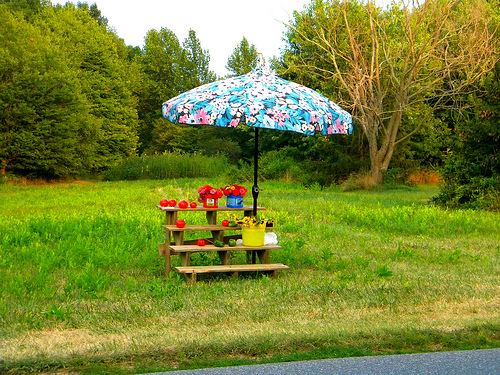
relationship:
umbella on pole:
[162, 52, 354, 136] [248, 126, 265, 263]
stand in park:
[160, 195, 275, 286] [17, 28, 455, 339]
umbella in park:
[162, 52, 354, 136] [17, 28, 455, 339]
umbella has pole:
[162, 52, 354, 136] [232, 119, 272, 220]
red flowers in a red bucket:
[197, 184, 219, 196] [202, 196, 220, 208]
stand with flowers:
[158, 206, 290, 284] [229, 209, 271, 245]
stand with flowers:
[158, 206, 290, 284] [221, 181, 246, 208]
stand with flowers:
[158, 206, 290, 284] [198, 182, 223, 205]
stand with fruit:
[158, 206, 290, 284] [198, 233, 208, 245]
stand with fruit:
[158, 206, 290, 284] [221, 217, 231, 228]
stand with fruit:
[158, 206, 290, 284] [173, 215, 187, 230]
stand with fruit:
[158, 206, 290, 284] [178, 197, 188, 208]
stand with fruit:
[158, 206, 290, 284] [159, 198, 169, 208]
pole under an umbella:
[252, 127, 259, 265] [162, 52, 354, 136]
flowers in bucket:
[193, 171, 255, 213] [227, 193, 244, 208]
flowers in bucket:
[198, 184, 248, 203] [230, 213, 275, 248]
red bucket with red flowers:
[203, 197, 218, 208] [198, 182, 218, 197]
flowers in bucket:
[226, 212, 276, 228] [239, 222, 266, 252]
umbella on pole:
[162, 52, 355, 134] [251, 125, 264, 213]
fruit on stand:
[178, 200, 188, 209] [151, 191, 293, 283]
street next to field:
[387, 351, 467, 373] [29, 195, 336, 373]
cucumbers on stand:
[212, 231, 241, 253] [131, 161, 350, 310]